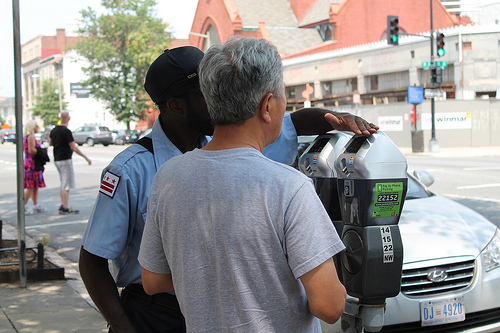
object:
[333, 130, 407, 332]
meter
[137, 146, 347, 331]
shirt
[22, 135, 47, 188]
dress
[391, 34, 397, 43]
light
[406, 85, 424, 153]
sign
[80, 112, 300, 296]
shirt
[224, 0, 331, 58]
roof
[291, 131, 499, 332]
car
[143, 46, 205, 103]
hat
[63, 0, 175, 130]
tree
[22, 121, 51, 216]
woman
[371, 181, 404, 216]
sticker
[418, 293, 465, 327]
license plate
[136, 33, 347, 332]
man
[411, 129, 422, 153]
pillar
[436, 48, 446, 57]
light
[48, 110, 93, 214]
man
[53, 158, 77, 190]
shorts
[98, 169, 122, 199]
patch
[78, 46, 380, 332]
people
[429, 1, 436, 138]
pole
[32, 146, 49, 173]
sweater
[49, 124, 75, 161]
shirt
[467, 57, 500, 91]
sign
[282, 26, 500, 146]
wall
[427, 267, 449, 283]
insignia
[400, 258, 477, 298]
grill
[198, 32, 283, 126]
hair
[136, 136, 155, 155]
strap